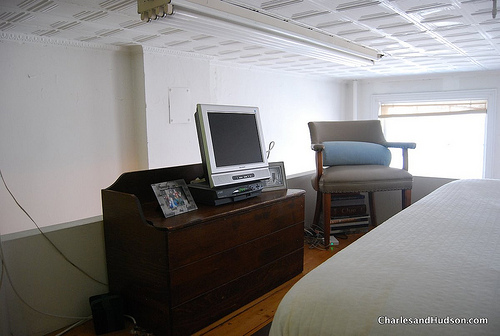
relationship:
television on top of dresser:
[189, 103, 272, 190] [100, 161, 305, 335]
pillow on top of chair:
[314, 140, 392, 167] [305, 117, 417, 250]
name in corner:
[375, 314, 489, 326] [363, 286, 499, 335]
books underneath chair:
[314, 191, 370, 233] [305, 117, 417, 250]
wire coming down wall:
[1, 172, 110, 288] [1, 32, 347, 335]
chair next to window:
[305, 117, 417, 250] [378, 100, 488, 181]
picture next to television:
[161, 185, 190, 209] [189, 103, 272, 190]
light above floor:
[329, 239, 335, 248] [39, 232, 371, 335]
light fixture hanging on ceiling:
[137, 0, 384, 71] [0, 0, 499, 81]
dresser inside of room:
[100, 161, 305, 335] [0, 1, 498, 335]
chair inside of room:
[305, 117, 417, 250] [0, 1, 498, 335]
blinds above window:
[375, 99, 487, 118] [378, 100, 488, 181]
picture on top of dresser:
[161, 185, 190, 209] [100, 161, 305, 335]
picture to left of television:
[161, 185, 190, 209] [189, 103, 272, 190]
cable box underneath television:
[190, 178, 265, 207] [189, 103, 272, 190]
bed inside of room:
[267, 176, 498, 335] [0, 1, 498, 335]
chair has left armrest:
[305, 117, 417, 250] [382, 139, 417, 172]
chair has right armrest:
[305, 117, 417, 250] [310, 140, 326, 184]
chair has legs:
[305, 117, 417, 250] [310, 189, 412, 250]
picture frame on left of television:
[151, 177, 198, 220] [189, 103, 272, 190]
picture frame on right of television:
[263, 159, 286, 194] [189, 103, 272, 190]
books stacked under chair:
[314, 191, 370, 233] [305, 117, 417, 250]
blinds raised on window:
[375, 99, 487, 118] [378, 100, 488, 181]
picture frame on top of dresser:
[151, 177, 198, 220] [100, 161, 305, 335]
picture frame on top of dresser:
[263, 159, 286, 194] [100, 161, 305, 335]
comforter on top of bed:
[263, 177, 499, 334] [267, 176, 498, 335]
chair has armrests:
[305, 117, 417, 250] [311, 140, 417, 175]